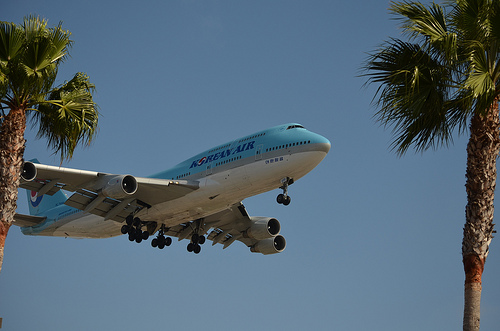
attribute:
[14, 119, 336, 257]
airplane — metal, large, landing, white, flying, low, coming, blue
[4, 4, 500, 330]
sky — blue, overhead, clear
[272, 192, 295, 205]
wheels — rubber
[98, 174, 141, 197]
engine — large, metal, clustered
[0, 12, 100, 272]
tree — palm, large, green, spotty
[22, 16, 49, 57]
leaves — green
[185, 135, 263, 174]
logo — air line, blue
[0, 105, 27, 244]
trunk — brown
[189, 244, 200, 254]
wheel — down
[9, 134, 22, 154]
bark — brown